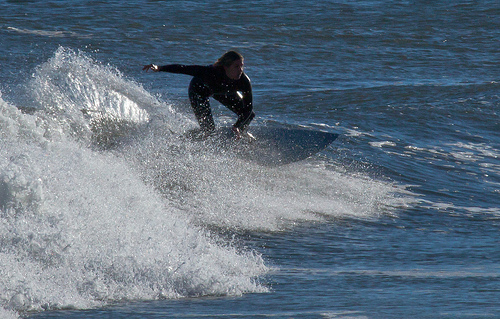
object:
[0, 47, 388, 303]
wave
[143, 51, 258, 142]
person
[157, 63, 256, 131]
suit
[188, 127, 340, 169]
surboard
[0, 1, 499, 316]
water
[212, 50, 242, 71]
hair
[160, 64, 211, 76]
arm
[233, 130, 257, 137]
feet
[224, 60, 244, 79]
face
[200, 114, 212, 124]
knees